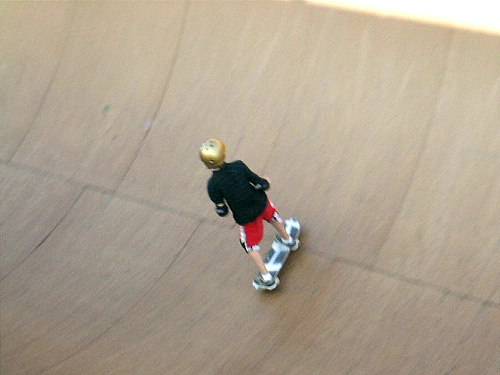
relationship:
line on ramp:
[329, 255, 496, 318] [1, 1, 196, 373]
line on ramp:
[73, 182, 203, 242] [189, 285, 361, 372]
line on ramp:
[3, 182, 96, 285] [304, 10, 499, 372]